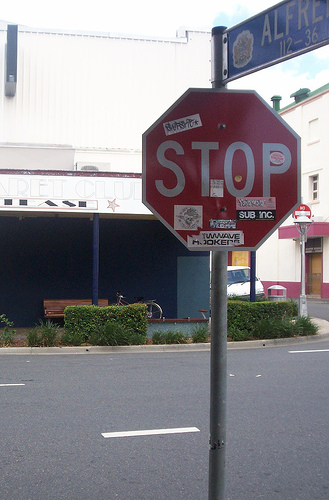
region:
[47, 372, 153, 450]
Gray pavement on road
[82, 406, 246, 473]
White stripe on a road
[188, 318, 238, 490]
silver pole holding up a stop sign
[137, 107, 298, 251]
Red and white stop sign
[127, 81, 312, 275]
Stop sign with stickers on it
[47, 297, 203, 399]
Green bush next to a road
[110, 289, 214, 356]
Bike parked by a building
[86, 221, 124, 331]
Blue pole on a building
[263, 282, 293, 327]
Trash can by a road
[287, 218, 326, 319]
Light pole by a road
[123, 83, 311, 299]
The stop sign is on a pole.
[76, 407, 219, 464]
There are white lines on the road.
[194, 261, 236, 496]
The pole the stop sign is on is grey.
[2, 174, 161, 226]
The name of the club on the building.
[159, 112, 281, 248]
Stickers on the stop sign.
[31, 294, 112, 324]
A bench against the building.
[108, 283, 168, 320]
There is a bike next to the bench.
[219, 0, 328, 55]
Street sign on top of the pole.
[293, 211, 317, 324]
There is a streetlight next to bushes.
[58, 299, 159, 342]
The bush is rectangular.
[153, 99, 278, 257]
part of a red stop sign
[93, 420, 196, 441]
a white line on the road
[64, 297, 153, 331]
part of a trimmed bush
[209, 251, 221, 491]
part of a metal pole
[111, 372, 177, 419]
part of plain road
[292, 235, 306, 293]
part of a metal pole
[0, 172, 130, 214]
part of some written art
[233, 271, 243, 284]
front window of a car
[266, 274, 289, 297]
part of litter bin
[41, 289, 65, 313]
part of a bench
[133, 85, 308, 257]
Red octagon shaped stop sign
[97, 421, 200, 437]
White line on a road.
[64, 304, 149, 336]
Green hedge along road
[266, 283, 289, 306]
gray trashcan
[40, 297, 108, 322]
wooden bench beside a bicycle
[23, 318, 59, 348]
Plant beside the road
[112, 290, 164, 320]
Bicycle sitting beside a bench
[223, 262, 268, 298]
White van with front visible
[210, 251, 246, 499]
Long gray pole to stop sign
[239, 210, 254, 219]
The word SUB in white writing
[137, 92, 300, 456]
city street with stop sign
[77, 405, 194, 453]
white line on street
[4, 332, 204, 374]
curb separates sidewalk from street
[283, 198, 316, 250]
do not enter sign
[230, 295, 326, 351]
bushes behind street corner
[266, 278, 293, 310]
cement style garbage can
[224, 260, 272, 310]
white van parked in far right of picture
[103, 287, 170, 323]
bicycle parked under building overhang in shade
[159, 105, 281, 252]
strange stickers are glued onto the stop sign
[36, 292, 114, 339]
wooden bench in shade